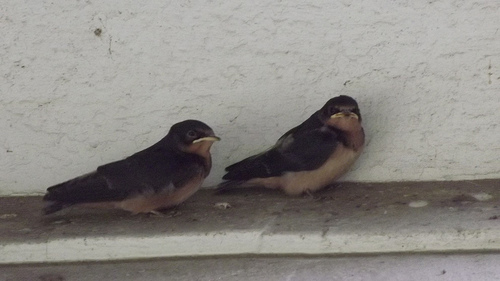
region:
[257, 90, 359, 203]
bird on the ledge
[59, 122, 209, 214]
bird on the ledge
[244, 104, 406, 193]
bird on the ledge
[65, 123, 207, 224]
bird on the ledge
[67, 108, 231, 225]
bird on the ledge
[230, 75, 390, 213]
bird on the ledge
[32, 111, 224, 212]
bird on the ledge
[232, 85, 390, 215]
bird on the ledge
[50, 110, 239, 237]
bird on the ledge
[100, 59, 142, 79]
this is the wall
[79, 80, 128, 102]
the wall is rough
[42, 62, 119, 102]
the wall is clean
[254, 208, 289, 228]
the area is clean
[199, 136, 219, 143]
this is a beak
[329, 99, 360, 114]
theses are the eyes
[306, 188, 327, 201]
this is a foot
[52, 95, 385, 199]
these are two birds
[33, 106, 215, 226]
a bird on the wall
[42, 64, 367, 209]
two birds sitting in the wall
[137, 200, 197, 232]
legs of the bird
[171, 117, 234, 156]
face of the bird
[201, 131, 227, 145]
nose of the bird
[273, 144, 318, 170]
fur of the bird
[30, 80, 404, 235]
Two small brown birds on ledge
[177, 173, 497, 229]
Bird droppings on ledge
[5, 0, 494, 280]
White and gray concrete wall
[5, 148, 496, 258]
Dirty gray concrete ledge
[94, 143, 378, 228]
Tan colored feathers on abdomens of small brown birds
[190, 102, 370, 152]
Light beaks with dark tips on small brown birds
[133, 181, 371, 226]
Tan or gray feet of small brown birds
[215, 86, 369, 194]
Bird looking at camera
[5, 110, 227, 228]
Bird facing the side not looking at camera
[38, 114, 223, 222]
Small bird on a sill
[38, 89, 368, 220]
Two same specie brirds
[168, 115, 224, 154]
Brown and beige bird's face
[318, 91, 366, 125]
Small bird looking towards the camera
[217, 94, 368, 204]
Dark brown and beige bird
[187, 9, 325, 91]
White stucco solid wall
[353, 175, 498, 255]
Dirty sill on a side wall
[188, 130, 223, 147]
Very small bird's peak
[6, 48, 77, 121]
Dirt on a white wall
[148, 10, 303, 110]
White irregular concrete wall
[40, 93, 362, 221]
bird is next to bird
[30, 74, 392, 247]
two birds facing to the right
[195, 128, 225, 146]
peak is gray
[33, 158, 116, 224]
the tail is long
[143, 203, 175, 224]
the legs are short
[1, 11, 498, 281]
birds are on a a roof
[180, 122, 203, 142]
the eye is black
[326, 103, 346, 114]
the eye is black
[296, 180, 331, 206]
legs are short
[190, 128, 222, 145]
beak on the bird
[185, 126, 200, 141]
black eye on the bird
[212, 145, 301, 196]
tail feathers on the bird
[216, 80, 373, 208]
Bird on the ledge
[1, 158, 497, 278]
Ledge on the building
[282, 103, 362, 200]
tan feathers on the chest of the bird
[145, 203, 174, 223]
foot on the bird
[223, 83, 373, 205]
black and brown feathers on the bird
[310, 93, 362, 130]
Head on the bird